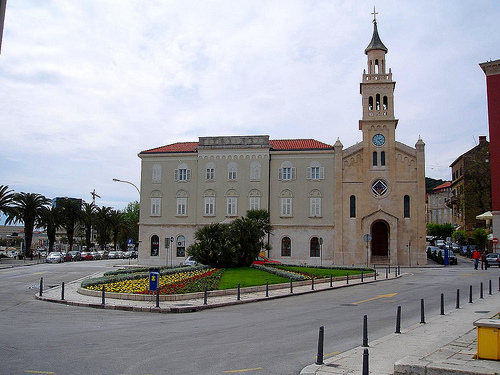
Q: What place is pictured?
A: It is a street.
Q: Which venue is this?
A: This is a street.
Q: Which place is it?
A: It is a street.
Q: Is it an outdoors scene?
A: Yes, it is outdoors.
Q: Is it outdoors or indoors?
A: It is outdoors.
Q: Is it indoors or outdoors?
A: It is outdoors.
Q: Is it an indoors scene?
A: No, it is outdoors.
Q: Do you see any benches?
A: No, there are no benches.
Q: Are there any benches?
A: No, there are no benches.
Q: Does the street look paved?
A: Yes, the street is paved.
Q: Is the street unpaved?
A: No, the street is paved.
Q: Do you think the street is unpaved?
A: No, the street is paved.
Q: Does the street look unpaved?
A: No, the street is paved.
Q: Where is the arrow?
A: The arrow is on the street.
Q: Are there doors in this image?
A: Yes, there is a door.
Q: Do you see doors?
A: Yes, there is a door.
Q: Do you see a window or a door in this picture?
A: Yes, there is a door.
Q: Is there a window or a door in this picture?
A: Yes, there is a door.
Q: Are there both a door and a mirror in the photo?
A: No, there is a door but no mirrors.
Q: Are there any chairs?
A: No, there are no chairs.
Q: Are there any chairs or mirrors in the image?
A: No, there are no chairs or mirrors.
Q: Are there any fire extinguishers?
A: No, there are no fire extinguishers.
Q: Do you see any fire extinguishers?
A: No, there are no fire extinguishers.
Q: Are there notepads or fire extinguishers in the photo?
A: No, there are no fire extinguishers or notepads.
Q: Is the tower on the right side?
A: Yes, the tower is on the right of the image.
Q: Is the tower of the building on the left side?
A: No, the tower is on the right of the image.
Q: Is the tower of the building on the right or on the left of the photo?
A: The tower is on the right of the image.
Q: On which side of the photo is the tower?
A: The tower is on the right of the image.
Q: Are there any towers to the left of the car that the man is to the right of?
A: Yes, there is a tower to the left of the car.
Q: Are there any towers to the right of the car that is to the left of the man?
A: No, the tower is to the left of the car.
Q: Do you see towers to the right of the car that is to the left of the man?
A: No, the tower is to the left of the car.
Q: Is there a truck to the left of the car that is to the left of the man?
A: No, there is a tower to the left of the car.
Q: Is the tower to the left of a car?
A: Yes, the tower is to the left of a car.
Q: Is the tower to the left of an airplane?
A: No, the tower is to the left of a car.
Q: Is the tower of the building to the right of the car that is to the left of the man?
A: No, the tower is to the left of the car.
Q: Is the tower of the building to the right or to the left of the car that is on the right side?
A: The tower is to the left of the car.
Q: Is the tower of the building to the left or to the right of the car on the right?
A: The tower is to the left of the car.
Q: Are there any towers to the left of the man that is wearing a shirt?
A: Yes, there is a tower to the left of the man.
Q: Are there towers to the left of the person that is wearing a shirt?
A: Yes, there is a tower to the left of the man.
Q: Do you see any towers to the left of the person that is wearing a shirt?
A: Yes, there is a tower to the left of the man.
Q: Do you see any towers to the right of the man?
A: No, the tower is to the left of the man.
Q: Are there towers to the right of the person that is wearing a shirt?
A: No, the tower is to the left of the man.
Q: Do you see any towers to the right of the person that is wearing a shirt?
A: No, the tower is to the left of the man.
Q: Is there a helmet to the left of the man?
A: No, there is a tower to the left of the man.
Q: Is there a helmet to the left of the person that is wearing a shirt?
A: No, there is a tower to the left of the man.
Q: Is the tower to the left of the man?
A: Yes, the tower is to the left of the man.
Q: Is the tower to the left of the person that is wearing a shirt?
A: Yes, the tower is to the left of the man.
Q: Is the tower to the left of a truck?
A: No, the tower is to the left of the man.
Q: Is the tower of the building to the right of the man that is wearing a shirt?
A: No, the tower is to the left of the man.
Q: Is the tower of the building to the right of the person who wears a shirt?
A: No, the tower is to the left of the man.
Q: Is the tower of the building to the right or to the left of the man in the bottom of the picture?
A: The tower is to the left of the man.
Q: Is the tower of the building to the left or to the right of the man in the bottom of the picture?
A: The tower is to the left of the man.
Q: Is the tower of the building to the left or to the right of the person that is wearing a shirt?
A: The tower is to the left of the man.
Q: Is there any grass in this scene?
A: Yes, there is grass.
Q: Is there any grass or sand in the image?
A: Yes, there is grass.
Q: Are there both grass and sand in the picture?
A: No, there is grass but no sand.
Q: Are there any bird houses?
A: No, there are no bird houses.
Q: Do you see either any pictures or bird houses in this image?
A: No, there are no bird houses or pictures.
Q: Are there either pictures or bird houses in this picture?
A: No, there are no bird houses or pictures.